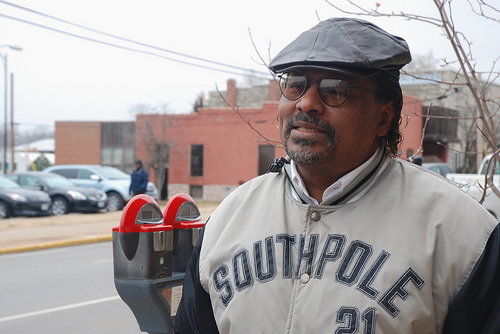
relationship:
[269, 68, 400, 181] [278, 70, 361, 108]
man has glasses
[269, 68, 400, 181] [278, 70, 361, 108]
man wearing sunglasses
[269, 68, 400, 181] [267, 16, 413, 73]
man wearing hat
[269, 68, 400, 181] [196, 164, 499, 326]
man wearing jacket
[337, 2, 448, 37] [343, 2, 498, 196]
branch on tree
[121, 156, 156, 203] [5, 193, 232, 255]
person on sidewalk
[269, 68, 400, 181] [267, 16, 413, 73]
man has hat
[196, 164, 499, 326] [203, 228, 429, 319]
jacket has words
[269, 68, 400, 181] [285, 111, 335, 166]
man has goatee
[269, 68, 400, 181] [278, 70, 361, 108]
man wearing glasses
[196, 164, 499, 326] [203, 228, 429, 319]
jacket says southpole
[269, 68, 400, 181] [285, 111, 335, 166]
man has facial hair